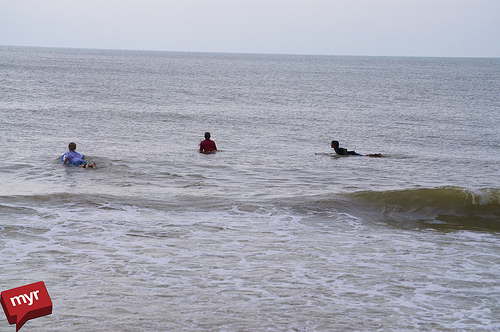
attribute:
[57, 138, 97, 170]
boy — swimming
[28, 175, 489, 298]
water — calm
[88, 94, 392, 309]
water — calm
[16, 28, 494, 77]
skyline — above water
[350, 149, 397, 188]
ground — with water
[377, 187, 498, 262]
wave — breaking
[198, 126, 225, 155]
swimmer — red 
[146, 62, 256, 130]
water — calm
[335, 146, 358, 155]
clothes — blue 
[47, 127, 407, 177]
surfers — in water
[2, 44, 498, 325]
water — calm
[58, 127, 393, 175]
swimmers — in water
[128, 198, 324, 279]
water — is where person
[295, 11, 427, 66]
sky — blue 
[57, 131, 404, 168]
swimmers — in water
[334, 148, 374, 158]
clothing — dark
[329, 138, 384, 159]
swimmer — swimming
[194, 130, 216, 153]
swimmer — swimming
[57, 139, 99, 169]
swimmer — swimming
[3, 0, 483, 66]
sky — cloudy